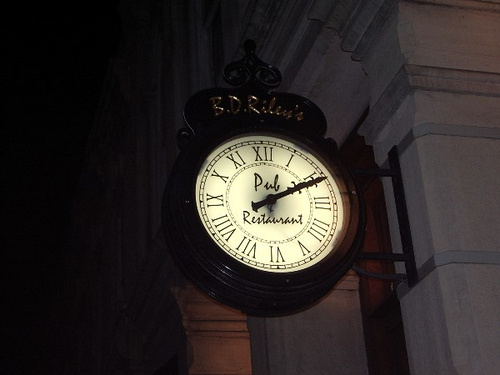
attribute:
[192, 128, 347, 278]
clock face — white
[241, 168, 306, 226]
script — black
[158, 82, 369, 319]
clock — white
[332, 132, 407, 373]
door — wooden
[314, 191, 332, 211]
letters — Capital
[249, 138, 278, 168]
12 — roman numeral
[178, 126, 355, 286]
clock — black, analog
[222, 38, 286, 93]
embellishment — nice, little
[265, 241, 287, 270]
numeral — 6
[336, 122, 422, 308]
mounting plate — black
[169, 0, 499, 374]
building — brick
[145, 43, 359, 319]
clock — wooden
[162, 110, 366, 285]
face — analog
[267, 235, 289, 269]
numerals — roman numerals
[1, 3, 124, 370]
sky — black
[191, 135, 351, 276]
clock — white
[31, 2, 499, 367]
building — gray, stone, old-fashioned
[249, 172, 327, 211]
hand — black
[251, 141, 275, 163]
roman numeral — XII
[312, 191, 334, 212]
roman numeral — 3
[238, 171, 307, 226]
text — Pub Restaurant